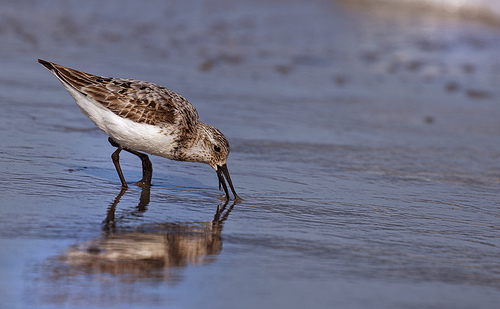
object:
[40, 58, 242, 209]
bird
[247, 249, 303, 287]
beach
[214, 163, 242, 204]
beek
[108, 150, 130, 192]
legs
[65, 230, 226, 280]
reflection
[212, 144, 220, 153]
eye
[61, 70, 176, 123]
wing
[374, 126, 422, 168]
water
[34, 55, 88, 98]
tail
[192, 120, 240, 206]
head